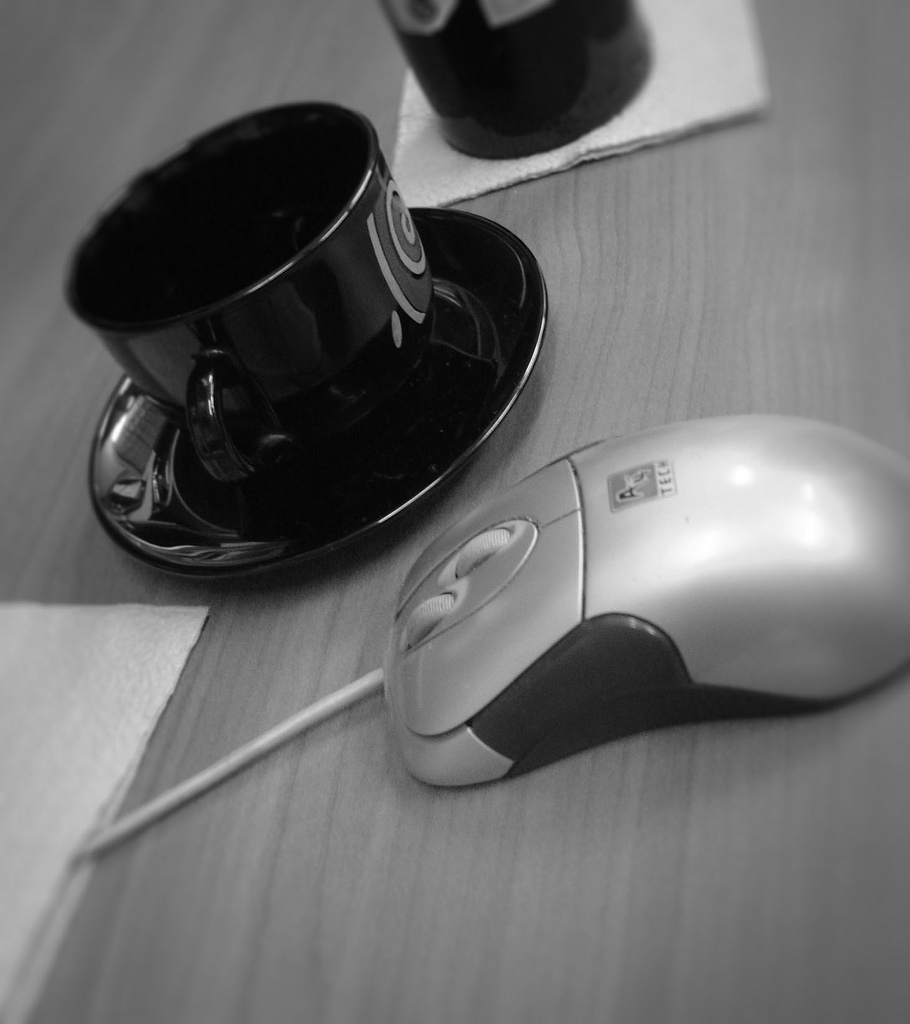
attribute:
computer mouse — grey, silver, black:
[384, 407, 904, 792]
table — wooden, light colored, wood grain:
[0, 0, 907, 1020]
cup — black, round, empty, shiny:
[58, 96, 435, 493]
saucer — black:
[88, 206, 550, 582]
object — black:
[385, 0, 655, 165]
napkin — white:
[392, 2, 775, 219]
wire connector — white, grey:
[64, 668, 380, 862]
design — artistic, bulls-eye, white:
[355, 176, 434, 352]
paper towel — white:
[3, 597, 214, 1022]